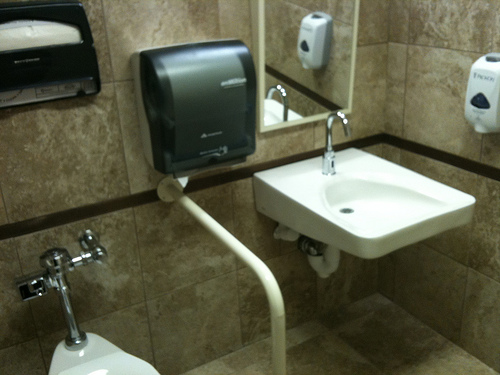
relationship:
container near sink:
[461, 52, 500, 136] [252, 147, 475, 258]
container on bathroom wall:
[128, 39, 261, 175] [1, 1, 389, 373]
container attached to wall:
[458, 49, 499, 139] [236, 2, 499, 344]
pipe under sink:
[263, 217, 341, 280] [250, 105, 479, 267]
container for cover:
[3, 6, 91, 105] [0, 18, 84, 52]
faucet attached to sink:
[321, 110, 351, 177] [252, 147, 475, 258]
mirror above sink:
[262, 1, 354, 126] [252, 147, 479, 279]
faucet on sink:
[321, 110, 351, 182] [252, 147, 475, 258]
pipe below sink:
[308, 244, 341, 280] [252, 147, 475, 258]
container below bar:
[128, 39, 261, 175] [178, 192, 288, 373]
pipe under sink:
[308, 244, 341, 280] [252, 147, 475, 258]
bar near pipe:
[178, 192, 288, 373] [308, 244, 341, 280]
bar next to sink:
[178, 192, 288, 373] [252, 147, 479, 279]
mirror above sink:
[262, 1, 354, 126] [252, 147, 475, 258]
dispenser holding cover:
[0, 3, 100, 109] [0, 18, 84, 52]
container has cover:
[0, 0, 101, 107] [6, 28, 83, 54]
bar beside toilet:
[178, 192, 288, 373] [16, 318, 183, 373]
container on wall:
[461, 52, 500, 136] [388, 18, 498, 171]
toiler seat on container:
[1, 17, 85, 53] [0, 0, 101, 107]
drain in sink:
[328, 192, 370, 223] [252, 147, 475, 258]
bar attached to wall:
[184, 204, 295, 308] [2, 2, 378, 365]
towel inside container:
[162, 47, 244, 157] [130, 37, 255, 172]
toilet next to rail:
[16, 233, 168, 373] [154, 173, 287, 370]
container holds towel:
[128, 27, 260, 173] [158, 47, 245, 164]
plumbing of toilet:
[13, 221, 120, 345] [50, 330, 159, 373]